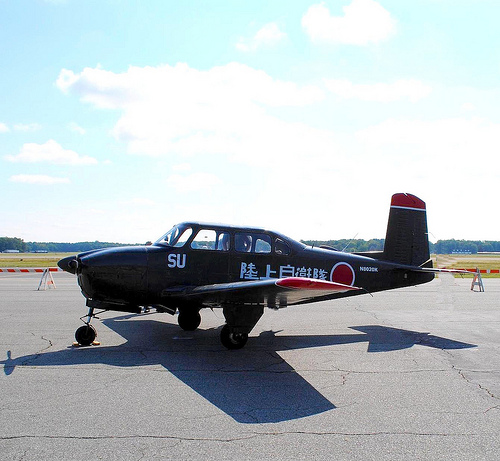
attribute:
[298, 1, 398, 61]
clouds — white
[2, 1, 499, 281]
sky — blue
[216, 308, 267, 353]
landing gear — rear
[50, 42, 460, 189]
clouds — white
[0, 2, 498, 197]
sky — blue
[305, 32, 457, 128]
sky — blue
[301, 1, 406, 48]
cloud — white, sky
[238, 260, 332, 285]
characters — Asian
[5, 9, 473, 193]
sky — blue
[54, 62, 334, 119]
clouds — white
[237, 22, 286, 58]
clouds — white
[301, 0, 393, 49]
clouds — white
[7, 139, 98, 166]
clouds — white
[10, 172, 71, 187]
clouds — white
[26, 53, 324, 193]
clouds — white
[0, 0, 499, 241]
sky — blue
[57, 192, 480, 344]
plane — old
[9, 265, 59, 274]
barriers — orange and white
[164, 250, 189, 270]
letters — white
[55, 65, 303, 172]
clouds — white